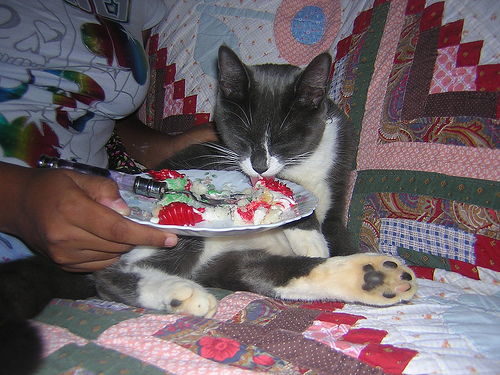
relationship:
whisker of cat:
[289, 149, 336, 175] [95, 45, 414, 318]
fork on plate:
[37, 153, 237, 208] [109, 163, 322, 241]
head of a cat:
[212, 44, 332, 186] [0, 42, 417, 373]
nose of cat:
[237, 146, 283, 185] [95, 45, 414, 318]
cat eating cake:
[95, 45, 414, 318] [145, 161, 317, 221]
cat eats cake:
[95, 45, 414, 318] [149, 174, 291, 219]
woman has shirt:
[0, 0, 219, 321] [1, 1, 168, 261]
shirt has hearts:
[1, 1, 168, 261] [9, 17, 70, 56]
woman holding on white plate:
[0, 0, 183, 305] [112, 159, 323, 241]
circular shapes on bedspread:
[272, 2, 354, 56] [270, 317, 421, 370]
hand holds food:
[22, 162, 184, 275] [135, 165, 297, 232]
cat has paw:
[95, 45, 414, 318] [337, 242, 422, 311]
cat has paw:
[95, 45, 414, 318] [157, 273, 219, 322]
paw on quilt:
[157, 273, 219, 322] [141, 2, 498, 361]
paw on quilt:
[337, 242, 422, 311] [141, 2, 498, 361]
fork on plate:
[37, 153, 237, 208] [104, 168, 316, 237]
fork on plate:
[37, 153, 246, 207] [104, 168, 316, 237]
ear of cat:
[292, 51, 332, 113] [0, 42, 417, 373]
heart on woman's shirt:
[12, 31, 46, 59] [1, 7, 158, 184]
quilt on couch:
[42, 2, 498, 375] [32, 0, 498, 372]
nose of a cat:
[248, 146, 270, 174] [0, 42, 417, 373]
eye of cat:
[223, 115, 259, 149] [83, 66, 423, 344]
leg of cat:
[287, 240, 421, 312] [95, 45, 414, 318]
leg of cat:
[91, 242, 224, 322] [95, 45, 414, 318]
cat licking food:
[190, 60, 391, 321] [139, 160, 283, 226]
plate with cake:
[104, 168, 316, 237] [145, 169, 295, 227]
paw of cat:
[350, 248, 422, 311] [0, 42, 417, 373]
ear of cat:
[289, 51, 332, 109] [165, 18, 407, 345]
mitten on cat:
[282, 227, 331, 258] [0, 42, 417, 373]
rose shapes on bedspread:
[192, 326, 267, 365] [81, 300, 450, 373]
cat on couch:
[95, 45, 414, 318] [112, 17, 499, 372]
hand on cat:
[106, 108, 227, 173] [95, 45, 414, 318]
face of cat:
[213, 47, 333, 179] [62, 45, 423, 307]